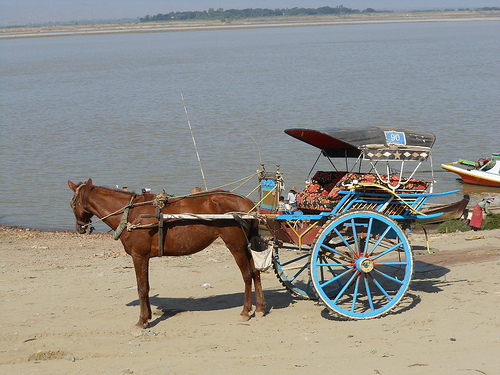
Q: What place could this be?
A: It is a road.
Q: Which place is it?
A: It is a road.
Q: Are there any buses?
A: No, there are no buses.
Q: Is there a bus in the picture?
A: No, there are no buses.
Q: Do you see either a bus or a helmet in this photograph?
A: No, there are no buses or helmets.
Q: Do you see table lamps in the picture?
A: No, there are no table lamps.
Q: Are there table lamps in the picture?
A: No, there are no table lamps.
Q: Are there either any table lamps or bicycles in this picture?
A: No, there are no table lamps or bicycles.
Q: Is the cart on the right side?
A: Yes, the cart is on the right of the image.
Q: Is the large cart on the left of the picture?
A: No, the cart is on the right of the image.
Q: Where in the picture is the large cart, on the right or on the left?
A: The cart is on the right of the image.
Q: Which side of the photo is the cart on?
A: The cart is on the right of the image.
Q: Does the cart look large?
A: Yes, the cart is large.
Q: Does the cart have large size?
A: Yes, the cart is large.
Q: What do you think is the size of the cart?
A: The cart is large.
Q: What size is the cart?
A: The cart is large.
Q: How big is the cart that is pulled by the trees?
A: The cart is large.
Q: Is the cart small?
A: No, the cart is large.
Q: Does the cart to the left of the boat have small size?
A: No, the cart is large.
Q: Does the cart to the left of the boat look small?
A: No, the cart is large.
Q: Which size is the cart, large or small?
A: The cart is large.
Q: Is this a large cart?
A: Yes, this is a large cart.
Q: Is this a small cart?
A: No, this is a large cart.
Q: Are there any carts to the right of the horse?
A: Yes, there is a cart to the right of the horse.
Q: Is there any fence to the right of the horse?
A: No, there is a cart to the right of the horse.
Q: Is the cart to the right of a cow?
A: No, the cart is to the right of the horse.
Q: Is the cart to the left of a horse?
A: No, the cart is to the right of a horse.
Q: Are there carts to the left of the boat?
A: Yes, there is a cart to the left of the boat.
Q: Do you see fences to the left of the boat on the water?
A: No, there is a cart to the left of the boat.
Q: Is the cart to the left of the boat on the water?
A: Yes, the cart is to the left of the boat.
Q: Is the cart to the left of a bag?
A: No, the cart is to the left of the boat.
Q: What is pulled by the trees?
A: The cart is pulled by the trees.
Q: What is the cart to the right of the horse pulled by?
A: The cart is pulled by the trees.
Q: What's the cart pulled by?
A: The cart is pulled by the trees.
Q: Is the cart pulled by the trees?
A: Yes, the cart is pulled by the trees.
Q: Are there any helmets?
A: No, there are no helmets.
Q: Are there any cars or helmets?
A: No, there are no helmets or cars.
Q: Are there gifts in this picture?
A: No, there are no gifts.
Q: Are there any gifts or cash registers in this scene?
A: No, there are no gifts or cash registers.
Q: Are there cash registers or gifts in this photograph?
A: No, there are no gifts or cash registers.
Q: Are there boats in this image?
A: Yes, there is a boat.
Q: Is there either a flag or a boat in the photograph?
A: Yes, there is a boat.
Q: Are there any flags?
A: No, there are no flags.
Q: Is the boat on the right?
A: Yes, the boat is on the right of the image.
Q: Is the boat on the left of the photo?
A: No, the boat is on the right of the image.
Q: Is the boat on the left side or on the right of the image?
A: The boat is on the right of the image.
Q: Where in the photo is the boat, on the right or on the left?
A: The boat is on the right of the image.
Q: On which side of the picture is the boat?
A: The boat is on the right of the image.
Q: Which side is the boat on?
A: The boat is on the right of the image.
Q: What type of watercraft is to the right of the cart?
A: The watercraft is a boat.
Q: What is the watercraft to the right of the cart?
A: The watercraft is a boat.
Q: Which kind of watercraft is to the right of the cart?
A: The watercraft is a boat.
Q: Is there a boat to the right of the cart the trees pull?
A: Yes, there is a boat to the right of the cart.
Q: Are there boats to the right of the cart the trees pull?
A: Yes, there is a boat to the right of the cart.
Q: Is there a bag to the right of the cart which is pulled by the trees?
A: No, there is a boat to the right of the cart.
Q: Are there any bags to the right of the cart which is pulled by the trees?
A: No, there is a boat to the right of the cart.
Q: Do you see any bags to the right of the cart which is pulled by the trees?
A: No, there is a boat to the right of the cart.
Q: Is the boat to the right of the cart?
A: Yes, the boat is to the right of the cart.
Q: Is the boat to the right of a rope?
A: No, the boat is to the right of the cart.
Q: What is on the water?
A: The boat is on the water.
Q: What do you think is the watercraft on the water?
A: The watercraft is a boat.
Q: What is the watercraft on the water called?
A: The watercraft is a boat.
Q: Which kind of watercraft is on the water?
A: The watercraft is a boat.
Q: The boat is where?
A: The boat is on the water.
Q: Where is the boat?
A: The boat is on the water.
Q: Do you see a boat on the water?
A: Yes, there is a boat on the water.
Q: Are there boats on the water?
A: Yes, there is a boat on the water.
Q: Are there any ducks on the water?
A: No, there is a boat on the water.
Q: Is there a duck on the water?
A: No, there is a boat on the water.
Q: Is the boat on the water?
A: Yes, the boat is on the water.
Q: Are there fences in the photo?
A: No, there are no fences.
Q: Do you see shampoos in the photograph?
A: No, there are no shampoos.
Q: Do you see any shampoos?
A: No, there are no shampoos.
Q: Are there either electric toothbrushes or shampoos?
A: No, there are no shampoos or electric toothbrushes.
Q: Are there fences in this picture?
A: No, there are no fences.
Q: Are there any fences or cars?
A: No, there are no fences or cars.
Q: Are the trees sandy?
A: Yes, the trees are sandy.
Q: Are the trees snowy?
A: No, the trees are sandy.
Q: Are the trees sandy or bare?
A: The trees are sandy.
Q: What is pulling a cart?
A: The trees are pulling a cart.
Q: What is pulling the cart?
A: The trees are pulling a cart.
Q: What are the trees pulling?
A: The trees are pulling a cart.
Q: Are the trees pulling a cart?
A: Yes, the trees are pulling a cart.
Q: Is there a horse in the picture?
A: Yes, there is a horse.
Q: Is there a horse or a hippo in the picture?
A: Yes, there is a horse.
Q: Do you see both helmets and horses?
A: No, there is a horse but no helmets.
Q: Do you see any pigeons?
A: No, there are no pigeons.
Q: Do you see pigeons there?
A: No, there are no pigeons.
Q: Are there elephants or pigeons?
A: No, there are no pigeons or elephants.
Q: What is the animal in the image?
A: The animal is a horse.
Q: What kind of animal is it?
A: The animal is a horse.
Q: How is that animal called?
A: This is a horse.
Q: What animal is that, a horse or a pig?
A: This is a horse.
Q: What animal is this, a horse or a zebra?
A: This is a horse.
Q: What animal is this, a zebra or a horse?
A: This is a horse.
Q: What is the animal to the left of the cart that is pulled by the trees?
A: The animal is a horse.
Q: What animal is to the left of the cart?
A: The animal is a horse.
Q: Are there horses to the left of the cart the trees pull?
A: Yes, there is a horse to the left of the cart.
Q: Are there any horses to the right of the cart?
A: No, the horse is to the left of the cart.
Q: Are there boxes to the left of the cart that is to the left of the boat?
A: No, there is a horse to the left of the cart.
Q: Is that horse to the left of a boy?
A: No, the horse is to the left of a cart.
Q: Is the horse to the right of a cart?
A: No, the horse is to the left of a cart.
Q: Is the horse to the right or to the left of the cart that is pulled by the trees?
A: The horse is to the left of the cart.